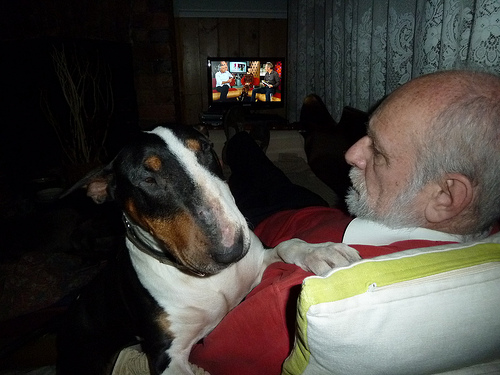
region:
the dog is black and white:
[101, 134, 300, 314]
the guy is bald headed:
[340, 93, 492, 239]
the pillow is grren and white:
[283, 265, 479, 363]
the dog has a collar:
[81, 144, 313, 354]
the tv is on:
[198, 48, 285, 108]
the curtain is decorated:
[300, 17, 441, 79]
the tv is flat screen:
[195, 50, 289, 113]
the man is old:
[266, 90, 486, 272]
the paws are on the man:
[269, 241, 361, 278]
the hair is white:
[450, 110, 492, 187]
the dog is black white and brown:
[15, 77, 295, 344]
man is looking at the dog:
[300, 60, 497, 257]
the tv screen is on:
[201, 52, 289, 114]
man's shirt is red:
[187, 186, 429, 373]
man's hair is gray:
[325, 61, 498, 243]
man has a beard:
[335, 156, 424, 238]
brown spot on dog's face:
[130, 147, 170, 174]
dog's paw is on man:
[244, 228, 355, 284]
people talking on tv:
[211, 60, 283, 99]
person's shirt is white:
[210, 66, 235, 94]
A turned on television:
[204, 53, 282, 108]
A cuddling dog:
[62, 118, 358, 371]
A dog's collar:
[119, 212, 165, 272]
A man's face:
[340, 70, 497, 232]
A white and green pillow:
[286, 229, 496, 366]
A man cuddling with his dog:
[76, 69, 498, 369]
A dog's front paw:
[279, 233, 359, 274]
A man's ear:
[425, 166, 473, 226]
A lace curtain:
[285, 0, 498, 117]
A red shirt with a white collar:
[194, 209, 435, 373]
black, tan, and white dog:
[67, 113, 367, 374]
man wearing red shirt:
[208, 58, 497, 366]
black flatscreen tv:
[209, 55, 286, 112]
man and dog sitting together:
[71, 75, 498, 373]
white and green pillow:
[282, 250, 498, 368]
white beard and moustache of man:
[345, 160, 425, 223]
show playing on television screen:
[209, 59, 277, 100]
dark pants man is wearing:
[231, 105, 355, 218]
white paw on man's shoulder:
[269, 232, 351, 283]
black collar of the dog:
[124, 222, 182, 263]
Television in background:
[194, 51, 299, 116]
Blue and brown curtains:
[349, 14, 409, 70]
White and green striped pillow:
[286, 266, 488, 373]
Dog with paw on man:
[71, 59, 491, 374]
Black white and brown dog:
[56, 128, 303, 373]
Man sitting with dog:
[34, 60, 496, 374]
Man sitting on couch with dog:
[62, 73, 493, 369]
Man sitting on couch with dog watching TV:
[28, 18, 495, 363]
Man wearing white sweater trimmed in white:
[254, 51, 488, 373]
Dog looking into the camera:
[66, 128, 323, 370]